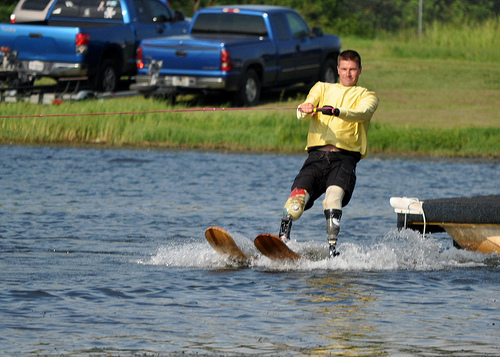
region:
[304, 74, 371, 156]
The yellow shirt the guy is wearing.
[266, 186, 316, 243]
The guy's left prosthetic leg.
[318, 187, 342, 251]
The guy's right prosthetic leg.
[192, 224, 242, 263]
The left wooden water ski.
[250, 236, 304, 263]
The right wooden water ski.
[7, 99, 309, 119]
The red rope the guy is holding on to.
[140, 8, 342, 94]
The blue truck on the right.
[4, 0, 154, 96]
The blue truck on the left.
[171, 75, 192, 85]
The license plate of the truck on the right.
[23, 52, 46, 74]
The license plate of the truck on the left.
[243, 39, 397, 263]
A man with no legs riding water skis.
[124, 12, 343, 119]
a parked blue truck.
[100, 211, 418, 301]
splay around a water skier.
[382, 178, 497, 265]
A dock near a water skier.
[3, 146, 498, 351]
A large body of water.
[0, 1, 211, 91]
A blue truck parked.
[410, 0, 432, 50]
a pole in a field of grass.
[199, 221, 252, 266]
a right side water ski.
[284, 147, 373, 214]
a pair of black shorts.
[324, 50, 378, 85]
a man with gray hair.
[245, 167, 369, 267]
The man has prosthetic legs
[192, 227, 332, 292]
The man is water skiing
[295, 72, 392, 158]
He is wearing a yellow shirt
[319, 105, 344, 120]
He has one prosthetic arm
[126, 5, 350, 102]
Truck is blue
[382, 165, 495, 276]
Dock in the water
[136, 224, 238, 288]
Water is splashing from skis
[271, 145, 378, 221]
Man wearing black shorts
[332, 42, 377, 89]
He has short hair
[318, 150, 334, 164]
Drawstring on shorts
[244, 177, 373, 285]
A man water skiing with prosthetic legs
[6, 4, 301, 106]
Two blue trucks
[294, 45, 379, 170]
A man wearing a yellow jacket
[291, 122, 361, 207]
A man wearing black shorts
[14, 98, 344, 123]
A red towline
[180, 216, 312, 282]
Two brown water skis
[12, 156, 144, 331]
Ripply blue water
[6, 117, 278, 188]
Green grass at waters edge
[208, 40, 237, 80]
A red tail light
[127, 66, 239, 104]
The silver bumper of a truck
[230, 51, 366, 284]
man on water skis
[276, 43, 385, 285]
man with prosthetic legs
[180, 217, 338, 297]
two water skis in water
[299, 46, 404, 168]
man wearing yellow top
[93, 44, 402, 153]
man holding red rope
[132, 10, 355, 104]
blue pick-up truck in grass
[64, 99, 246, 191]
grass along bank of water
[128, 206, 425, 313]
waves in the water from skier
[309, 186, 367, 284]
black, grey, and white prosthetic leg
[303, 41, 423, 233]
guy wearing black swim trunks